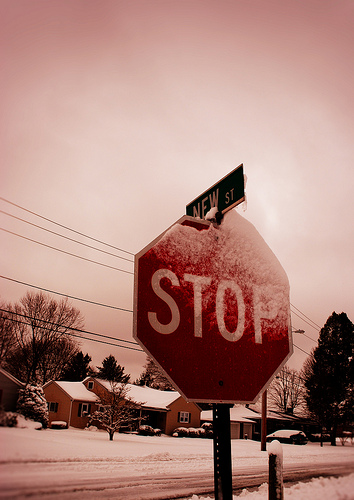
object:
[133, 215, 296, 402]
sign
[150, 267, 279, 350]
stop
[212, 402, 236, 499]
pole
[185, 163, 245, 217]
sign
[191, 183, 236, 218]
new st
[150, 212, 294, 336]
snow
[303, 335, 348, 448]
tree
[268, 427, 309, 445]
car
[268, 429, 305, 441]
snow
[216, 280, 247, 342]
letter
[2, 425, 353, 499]
ground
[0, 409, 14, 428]
bush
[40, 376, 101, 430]
house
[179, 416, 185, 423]
window